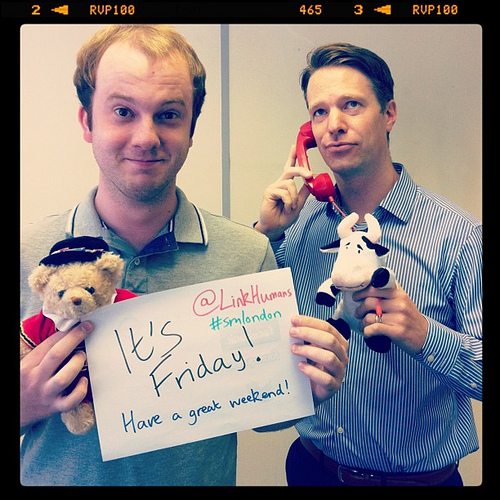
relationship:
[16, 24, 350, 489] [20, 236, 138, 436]
man holding bear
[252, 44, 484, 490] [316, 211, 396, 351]
man holding cow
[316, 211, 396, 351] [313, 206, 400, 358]
cow h cow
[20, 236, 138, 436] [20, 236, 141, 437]
bear in a costume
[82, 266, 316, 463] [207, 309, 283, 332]
sign has hash tags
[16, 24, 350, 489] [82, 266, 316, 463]
man holding sign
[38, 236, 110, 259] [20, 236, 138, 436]
cap on bear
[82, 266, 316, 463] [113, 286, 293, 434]
sign has words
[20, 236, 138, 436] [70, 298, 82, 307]
bear has a nose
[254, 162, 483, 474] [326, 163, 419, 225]
shirt has a collar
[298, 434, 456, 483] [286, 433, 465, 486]
belt on pants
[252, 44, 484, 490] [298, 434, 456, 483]
man wearing a belt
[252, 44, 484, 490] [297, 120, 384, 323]
man holding phone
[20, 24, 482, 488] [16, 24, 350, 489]
wall behind man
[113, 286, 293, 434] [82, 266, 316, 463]
words on sign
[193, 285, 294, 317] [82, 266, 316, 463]
twitter name on sign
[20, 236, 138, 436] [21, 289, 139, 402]
bear has a jacket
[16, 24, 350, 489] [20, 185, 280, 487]
man wearing a polo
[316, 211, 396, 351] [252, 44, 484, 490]
cow being held by man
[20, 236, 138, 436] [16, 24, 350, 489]
bear carried by man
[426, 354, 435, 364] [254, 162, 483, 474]
button on shirt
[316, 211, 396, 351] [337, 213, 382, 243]
cow has horns